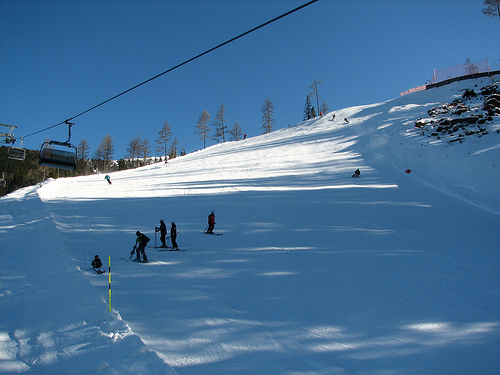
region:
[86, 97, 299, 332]
this is a ski slope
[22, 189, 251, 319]
this is a group of skiers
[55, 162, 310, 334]
the skiers are wearing black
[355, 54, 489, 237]
this is a mountain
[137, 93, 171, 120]
the sky is very clear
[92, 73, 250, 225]
the trees are old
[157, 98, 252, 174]
these are some pine trees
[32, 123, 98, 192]
this is a chair lift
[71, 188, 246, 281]
group of people skiing on snow covered hill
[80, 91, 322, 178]
line of green trees bordering snow covered hil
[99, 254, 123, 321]
striped pole erected in snow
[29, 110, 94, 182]
ski lift chair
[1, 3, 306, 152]
black support line for ski lift chairs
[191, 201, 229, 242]
person on skis on snow covered hill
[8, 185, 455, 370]
black shadow across surface of white snow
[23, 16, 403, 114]
blue cloudless sky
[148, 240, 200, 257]
pair skis on feet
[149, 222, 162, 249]
ski pole in someone's hand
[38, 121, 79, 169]
chair on ski lift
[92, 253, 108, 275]
person riding on sled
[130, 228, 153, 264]
person standing in the snow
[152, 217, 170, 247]
skier standing next to skier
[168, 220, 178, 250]
skier standing next to skier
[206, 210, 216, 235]
skier on ski slope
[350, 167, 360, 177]
person skiing down slope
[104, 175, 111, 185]
person skiing down slope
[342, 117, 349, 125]
person skiing down slope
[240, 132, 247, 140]
person skiing down slope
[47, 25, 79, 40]
white clouds in blue sky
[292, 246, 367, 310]
white snow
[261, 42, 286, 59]
white clouds in blue sky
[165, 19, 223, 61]
white clouds in blue sky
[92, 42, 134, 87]
white clouds in blue sky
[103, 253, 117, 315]
yellow and black pole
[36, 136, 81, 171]
ski lift over mountain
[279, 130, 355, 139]
dark shadow in snow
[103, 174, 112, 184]
person skiing down mountain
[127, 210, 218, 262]
group of people skiing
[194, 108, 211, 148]
bare trees in sky line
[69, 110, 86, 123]
cable for ski lift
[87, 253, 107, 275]
person sitting in snow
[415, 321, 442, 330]
sun light shining onto snow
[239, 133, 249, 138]
person on top of mountain